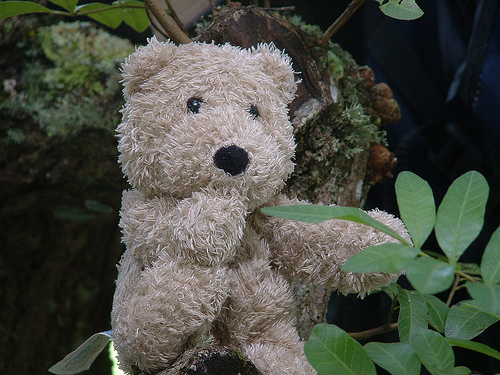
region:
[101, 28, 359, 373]
brown fuzzy teddy bear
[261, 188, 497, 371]
green leaves of plant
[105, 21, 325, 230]
teddy bear face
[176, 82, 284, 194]
eyes and nose of brown teddy bear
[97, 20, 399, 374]
light brown plush bear with one paw up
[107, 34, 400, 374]
light brown plush stuffed toy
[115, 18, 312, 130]
eyes and ears of teddy bear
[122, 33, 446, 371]
teddy bear near leaves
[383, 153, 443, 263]
one green leaf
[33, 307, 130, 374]
tag from plush stuffed animal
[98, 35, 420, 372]
the teddy bear looks a little worse for wear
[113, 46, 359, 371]
he appears to be saying "oops"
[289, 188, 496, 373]
the green plant make a lovely addition to the photo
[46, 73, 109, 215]
a pattern of flowers are in the background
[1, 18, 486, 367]
this could have been taken outside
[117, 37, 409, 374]
the bear is beige & shaggy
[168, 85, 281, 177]
his eyes & nose are black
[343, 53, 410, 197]
these could be butterflies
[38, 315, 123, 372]
the bear has a tag on him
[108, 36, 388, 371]
the teddy is someone's favorite toy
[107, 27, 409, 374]
The teddy bear is cream colored.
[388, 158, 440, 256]
The leaf is green.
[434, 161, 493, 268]
The leaf is green.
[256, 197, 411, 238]
The leaf is green.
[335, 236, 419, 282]
The leaf is green.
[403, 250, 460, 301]
The leaf is green.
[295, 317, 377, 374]
The leaf is green.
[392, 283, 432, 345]
The leaf is green.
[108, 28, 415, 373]
The teddy bear is stuffed.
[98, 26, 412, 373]
Tghe teddy bear has a black nose.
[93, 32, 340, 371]
a tan teddy bear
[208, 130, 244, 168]
black nose on bear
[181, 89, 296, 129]
two black eyes of bear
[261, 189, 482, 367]
green leaves in front of bear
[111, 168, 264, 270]
one arm near mouth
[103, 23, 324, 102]
two small ears of bear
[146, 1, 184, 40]
a stick behind the bear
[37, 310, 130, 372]
a tag coming from back of bear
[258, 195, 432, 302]
one arm sticking out to the right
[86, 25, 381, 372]
one lonely teddy bear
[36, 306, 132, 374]
tag on stuffed animal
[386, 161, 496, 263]
two green leaves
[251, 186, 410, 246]
leaf from house plant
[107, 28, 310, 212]
face of stuffed teddy bear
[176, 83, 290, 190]
eyes and nose of teddy bear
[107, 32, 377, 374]
light brown stuffed animal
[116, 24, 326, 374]
teddy bear with one paw to mouth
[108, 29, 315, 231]
teddy bear with light reflected in eye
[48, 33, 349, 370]
teddy bear with tag attached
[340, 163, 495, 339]
green leaves of house plant